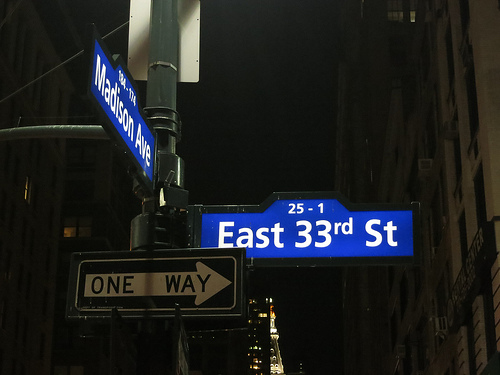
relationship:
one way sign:
[86, 273, 136, 296] [72, 250, 243, 317]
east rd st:
[217, 222, 286, 250] [363, 219, 399, 246]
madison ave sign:
[89, 51, 135, 144] [86, 23, 156, 190]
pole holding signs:
[129, 0, 185, 368] [82, 0, 417, 322]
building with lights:
[335, 1, 495, 371] [386, 1, 418, 25]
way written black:
[164, 274, 210, 294] [147, 261, 182, 271]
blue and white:
[86, 23, 156, 190] [97, 55, 152, 166]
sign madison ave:
[86, 23, 156, 190] [136, 121, 152, 169]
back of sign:
[131, 1, 198, 81] [72, 250, 243, 317]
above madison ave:
[83, 1, 249, 80] [136, 121, 152, 169]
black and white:
[147, 261, 182, 271] [144, 279, 162, 292]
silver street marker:
[129, 0, 185, 368] [132, 0, 205, 291]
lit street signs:
[185, 204, 421, 265] [82, 0, 417, 322]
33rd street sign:
[295, 217, 359, 252] [185, 204, 421, 265]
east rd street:
[217, 222, 286, 250] [361, 212, 414, 254]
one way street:
[86, 273, 136, 296] [72, 250, 243, 317]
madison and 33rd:
[89, 51, 135, 144] [295, 217, 359, 252]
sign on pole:
[72, 250, 243, 317] [129, 0, 185, 368]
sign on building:
[435, 223, 492, 344] [335, 1, 495, 371]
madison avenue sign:
[89, 51, 135, 144] [86, 23, 156, 190]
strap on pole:
[146, 61, 180, 72] [129, 0, 185, 368]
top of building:
[328, 2, 499, 57] [335, 1, 495, 371]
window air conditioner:
[441, 107, 463, 163] [443, 119, 457, 140]